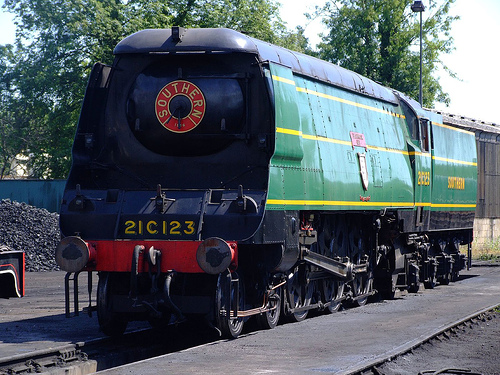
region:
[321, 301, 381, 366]
a smooth grey ground.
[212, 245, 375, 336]
black wheels on a train.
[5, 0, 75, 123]
the trees are green.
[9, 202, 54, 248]
a pile of grey rocks.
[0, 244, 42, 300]
a red and black railing.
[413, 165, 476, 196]
a train has yellow numbers and letters .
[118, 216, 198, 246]
the trains number is 2lcl23.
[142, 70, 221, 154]
the train says southern.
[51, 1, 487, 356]
a red yellow green and black train.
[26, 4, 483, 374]
a train is parked in the sunrise.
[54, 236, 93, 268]
the black and red metal front train bumper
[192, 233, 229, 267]
the black and red metal front train bumper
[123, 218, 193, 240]
the yellow numbers on a train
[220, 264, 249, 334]
a black round train wheel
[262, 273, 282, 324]
a black round train wheel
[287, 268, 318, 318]
a black round train wheel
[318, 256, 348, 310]
a black round train wheel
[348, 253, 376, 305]
a black round train wheel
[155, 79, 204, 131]
the red circle logo on the train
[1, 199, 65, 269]
a pile of grey rocks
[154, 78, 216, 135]
name of the railroad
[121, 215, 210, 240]
number on front of train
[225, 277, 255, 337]
wheel on the train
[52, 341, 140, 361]
part of railroad track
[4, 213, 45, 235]
a pile of rocks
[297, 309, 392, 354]
part of the sidewalk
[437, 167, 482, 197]
words on side of train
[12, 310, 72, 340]
reflection of the train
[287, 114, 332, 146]
yellow stripe on train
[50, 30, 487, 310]
train on railroad track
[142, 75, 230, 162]
Yellow circle on back of train.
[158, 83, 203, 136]
Yellow writing in red circle.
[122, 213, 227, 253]
Yellow writing on back of train.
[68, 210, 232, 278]
Red stripe on back of train.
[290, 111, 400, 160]
Yellow stripes on side of train.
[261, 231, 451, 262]
Wheels are black on train.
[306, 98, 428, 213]
Train car is mainly green.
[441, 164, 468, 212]
Yellow writing on side of train.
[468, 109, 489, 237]
Building in distance behind train.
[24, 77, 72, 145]
Leaves on trees are green.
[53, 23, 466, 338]
A green train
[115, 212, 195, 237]
The production number of the train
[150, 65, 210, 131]
branding on the train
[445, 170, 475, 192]
branding on the train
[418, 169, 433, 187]
The production number of the train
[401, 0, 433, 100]
A tall street light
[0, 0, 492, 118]
A cloudy sky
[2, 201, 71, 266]
A pile of coal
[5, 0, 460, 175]
Some trees behind the train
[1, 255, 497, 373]
some railroad tracks